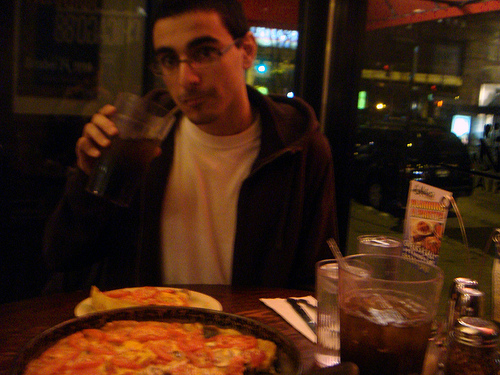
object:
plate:
[72, 285, 223, 320]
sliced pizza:
[79, 281, 204, 311]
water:
[315, 266, 371, 368]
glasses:
[148, 38, 240, 78]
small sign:
[397, 177, 453, 273]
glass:
[335, 252, 445, 374]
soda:
[337, 286, 433, 373]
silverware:
[285, 293, 327, 337]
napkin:
[256, 293, 316, 343]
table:
[0, 287, 317, 374]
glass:
[310, 256, 366, 372]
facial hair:
[182, 110, 220, 127]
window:
[249, 26, 300, 52]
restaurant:
[0, 1, 500, 374]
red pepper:
[445, 349, 497, 372]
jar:
[441, 314, 497, 374]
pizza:
[25, 317, 277, 374]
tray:
[9, 304, 300, 374]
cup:
[87, 91, 182, 209]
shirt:
[162, 114, 263, 289]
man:
[40, 3, 338, 300]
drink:
[88, 86, 178, 211]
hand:
[75, 104, 166, 178]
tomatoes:
[186, 343, 196, 355]